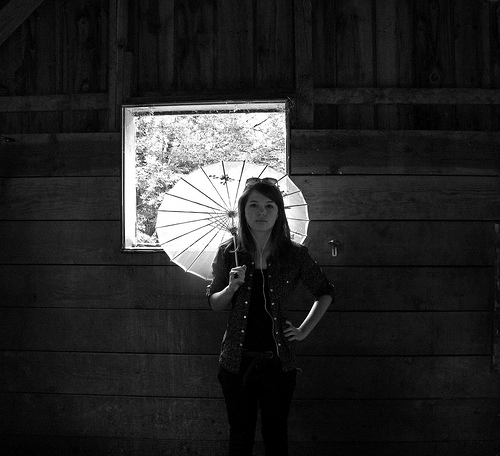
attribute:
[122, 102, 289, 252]
window — square, box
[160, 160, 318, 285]
umbrella — white, open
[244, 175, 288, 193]
sunglasses — pair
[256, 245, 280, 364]
wire — white colored, headphone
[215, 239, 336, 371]
shirt — button up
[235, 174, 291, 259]
hair — dark colored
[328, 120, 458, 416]
wall — wooden, paneled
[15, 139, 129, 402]
wall — paneled, wooden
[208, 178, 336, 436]
girl — young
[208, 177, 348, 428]
girl — young